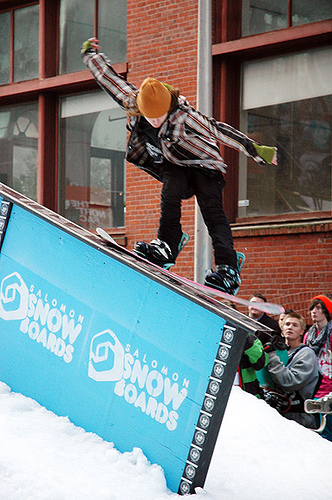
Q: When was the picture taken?
A: Daytime.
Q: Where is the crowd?
A: To the right.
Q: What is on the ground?
A: Snow.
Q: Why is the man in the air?
A: Snowboarding.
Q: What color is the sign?
A: Blue.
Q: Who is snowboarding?
A: The man.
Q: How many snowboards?
A: 1.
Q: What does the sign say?
A: Salomon Snowboards.